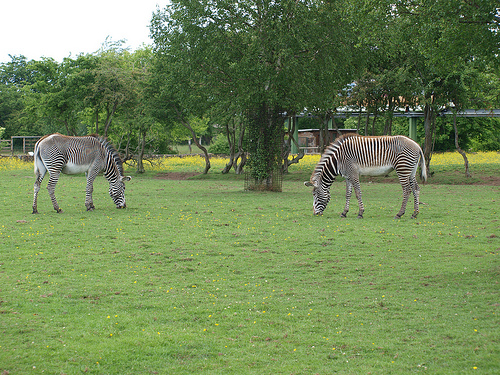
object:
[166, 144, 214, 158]
wall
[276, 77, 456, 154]
building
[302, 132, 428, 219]
zebra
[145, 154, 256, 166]
yellow flowers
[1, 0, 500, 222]
background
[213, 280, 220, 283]
flower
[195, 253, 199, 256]
flower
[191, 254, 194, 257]
flower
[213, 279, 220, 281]
flower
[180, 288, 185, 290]
flower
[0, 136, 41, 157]
fence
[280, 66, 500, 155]
shelter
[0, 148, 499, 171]
dandelions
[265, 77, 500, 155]
house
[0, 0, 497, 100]
sky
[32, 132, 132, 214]
zebra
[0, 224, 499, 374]
field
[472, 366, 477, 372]
flowers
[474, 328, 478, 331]
flowers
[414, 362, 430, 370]
flowers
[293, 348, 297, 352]
flowers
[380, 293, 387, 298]
flowers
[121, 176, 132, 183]
ear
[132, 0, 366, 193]
trees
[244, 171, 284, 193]
foilage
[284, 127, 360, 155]
fence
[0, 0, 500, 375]
park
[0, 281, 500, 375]
grass